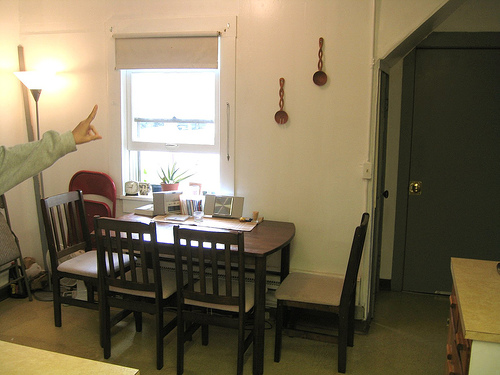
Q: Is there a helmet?
A: No, there are no helmets.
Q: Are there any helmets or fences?
A: No, there are no helmets or fences.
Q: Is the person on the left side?
A: Yes, the person is on the left of the image.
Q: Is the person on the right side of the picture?
A: No, the person is on the left of the image.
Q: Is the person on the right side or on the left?
A: The person is on the left of the image.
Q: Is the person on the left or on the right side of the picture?
A: The person is on the left of the image.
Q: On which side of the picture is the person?
A: The person is on the left of the image.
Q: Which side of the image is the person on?
A: The person is on the left of the image.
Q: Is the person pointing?
A: Yes, the person is pointing.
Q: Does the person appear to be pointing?
A: Yes, the person is pointing.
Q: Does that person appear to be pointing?
A: Yes, the person is pointing.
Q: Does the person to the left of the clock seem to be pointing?
A: Yes, the person is pointing.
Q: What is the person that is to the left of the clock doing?
A: The person is pointing.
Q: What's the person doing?
A: The person is pointing.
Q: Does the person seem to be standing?
A: No, the person is pointing.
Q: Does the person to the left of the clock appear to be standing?
A: No, the person is pointing.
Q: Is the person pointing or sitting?
A: The person is pointing.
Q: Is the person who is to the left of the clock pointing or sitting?
A: The person is pointing.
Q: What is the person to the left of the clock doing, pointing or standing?
A: The person is pointing.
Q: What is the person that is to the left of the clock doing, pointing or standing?
A: The person is pointing.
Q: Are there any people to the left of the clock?
A: Yes, there is a person to the left of the clock.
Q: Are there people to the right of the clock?
A: No, the person is to the left of the clock.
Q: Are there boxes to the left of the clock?
A: No, there is a person to the left of the clock.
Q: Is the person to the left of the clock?
A: Yes, the person is to the left of the clock.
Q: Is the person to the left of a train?
A: No, the person is to the left of the clock.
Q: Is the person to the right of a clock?
A: No, the person is to the left of a clock.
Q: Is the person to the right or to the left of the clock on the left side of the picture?
A: The person is to the left of the clock.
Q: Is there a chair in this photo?
A: Yes, there is a chair.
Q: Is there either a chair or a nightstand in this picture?
A: Yes, there is a chair.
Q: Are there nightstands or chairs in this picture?
A: Yes, there is a chair.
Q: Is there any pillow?
A: No, there are no pillows.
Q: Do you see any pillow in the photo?
A: No, there are no pillows.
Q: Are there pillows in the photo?
A: No, there are no pillows.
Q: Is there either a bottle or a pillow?
A: No, there are no pillows or bottles.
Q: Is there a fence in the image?
A: No, there are no fences.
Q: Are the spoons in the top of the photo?
A: Yes, the spoons are in the top of the image.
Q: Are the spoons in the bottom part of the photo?
A: No, the spoons are in the top of the image.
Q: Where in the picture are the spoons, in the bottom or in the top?
A: The spoons are in the top of the image.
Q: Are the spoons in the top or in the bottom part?
A: The spoons are in the top of the image.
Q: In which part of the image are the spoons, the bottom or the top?
A: The spoons are in the top of the image.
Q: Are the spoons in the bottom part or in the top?
A: The spoons are in the top of the image.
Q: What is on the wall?
A: The spoons are on the wall.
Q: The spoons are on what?
A: The spoons are on the wall.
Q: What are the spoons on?
A: The spoons are on the wall.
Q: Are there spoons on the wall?
A: Yes, there are spoons on the wall.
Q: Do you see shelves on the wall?
A: No, there are spoons on the wall.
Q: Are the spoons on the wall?
A: Yes, the spoons are on the wall.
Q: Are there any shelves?
A: No, there are no shelves.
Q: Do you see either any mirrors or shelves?
A: No, there are no shelves or mirrors.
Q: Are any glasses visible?
A: No, there are no glasses.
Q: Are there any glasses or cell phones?
A: No, there are no glasses or cell phones.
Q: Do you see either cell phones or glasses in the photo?
A: No, there are no glasses or cell phones.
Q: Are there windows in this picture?
A: Yes, there is a window.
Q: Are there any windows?
A: Yes, there is a window.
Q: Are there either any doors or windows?
A: Yes, there is a window.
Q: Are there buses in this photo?
A: No, there are no buses.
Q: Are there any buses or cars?
A: No, there are no buses or cars.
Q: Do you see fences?
A: No, there are no fences.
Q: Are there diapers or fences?
A: No, there are no fences or diapers.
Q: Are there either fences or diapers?
A: No, there are no fences or diapers.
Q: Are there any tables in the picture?
A: Yes, there is a table.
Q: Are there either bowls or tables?
A: Yes, there is a table.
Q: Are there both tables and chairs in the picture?
A: Yes, there are both a table and chairs.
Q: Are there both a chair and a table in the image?
A: Yes, there are both a table and a chair.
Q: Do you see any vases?
A: No, there are no vases.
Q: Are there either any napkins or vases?
A: No, there are no vases or napkins.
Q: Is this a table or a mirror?
A: This is a table.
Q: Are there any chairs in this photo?
A: Yes, there is a chair.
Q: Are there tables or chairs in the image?
A: Yes, there is a chair.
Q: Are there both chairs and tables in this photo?
A: Yes, there are both a chair and a table.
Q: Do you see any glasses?
A: No, there are no glasses.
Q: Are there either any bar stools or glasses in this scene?
A: No, there are no glasses or bar stools.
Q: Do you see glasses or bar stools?
A: No, there are no glasses or bar stools.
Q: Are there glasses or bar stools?
A: No, there are no glasses or bar stools.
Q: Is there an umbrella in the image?
A: No, there are no umbrellas.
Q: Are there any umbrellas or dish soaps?
A: No, there are no umbrellas or dish soaps.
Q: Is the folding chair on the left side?
A: Yes, the folding chair is on the left of the image.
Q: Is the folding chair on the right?
A: No, the folding chair is on the left of the image.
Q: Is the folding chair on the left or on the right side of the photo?
A: The folding chair is on the left of the image.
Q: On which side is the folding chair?
A: The folding chair is on the left of the image.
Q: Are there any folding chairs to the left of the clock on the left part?
A: Yes, there is a folding chair to the left of the clock.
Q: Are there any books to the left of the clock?
A: No, there is a folding chair to the left of the clock.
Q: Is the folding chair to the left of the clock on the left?
A: Yes, the folding chair is to the left of the clock.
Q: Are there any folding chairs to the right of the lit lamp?
A: Yes, there is a folding chair to the right of the lamp.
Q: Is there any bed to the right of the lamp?
A: No, there is a folding chair to the right of the lamp.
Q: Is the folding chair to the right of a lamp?
A: Yes, the folding chair is to the right of a lamp.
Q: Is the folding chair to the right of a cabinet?
A: No, the folding chair is to the right of a lamp.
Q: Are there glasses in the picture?
A: No, there are no glasses.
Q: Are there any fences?
A: No, there are no fences.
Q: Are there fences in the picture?
A: No, there are no fences.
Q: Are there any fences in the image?
A: No, there are no fences.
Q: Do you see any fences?
A: No, there are no fences.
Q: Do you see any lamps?
A: Yes, there is a lamp.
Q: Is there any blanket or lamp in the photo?
A: Yes, there is a lamp.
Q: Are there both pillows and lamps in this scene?
A: No, there is a lamp but no pillows.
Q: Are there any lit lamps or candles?
A: Yes, there is a lit lamp.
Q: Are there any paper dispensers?
A: No, there are no paper dispensers.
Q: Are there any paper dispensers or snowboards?
A: No, there are no paper dispensers or snowboards.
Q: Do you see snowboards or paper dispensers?
A: No, there are no paper dispensers or snowboards.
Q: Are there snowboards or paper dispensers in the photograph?
A: No, there are no paper dispensers or snowboards.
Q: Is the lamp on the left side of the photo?
A: Yes, the lamp is on the left of the image.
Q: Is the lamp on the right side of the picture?
A: No, the lamp is on the left of the image.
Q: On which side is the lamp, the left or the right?
A: The lamp is on the left of the image.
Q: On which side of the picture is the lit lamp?
A: The lamp is on the left of the image.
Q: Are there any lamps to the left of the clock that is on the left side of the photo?
A: Yes, there is a lamp to the left of the clock.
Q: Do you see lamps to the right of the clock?
A: No, the lamp is to the left of the clock.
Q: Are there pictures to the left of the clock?
A: No, there is a lamp to the left of the clock.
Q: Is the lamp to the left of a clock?
A: Yes, the lamp is to the left of a clock.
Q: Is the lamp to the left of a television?
A: No, the lamp is to the left of a clock.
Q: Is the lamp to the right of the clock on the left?
A: No, the lamp is to the left of the clock.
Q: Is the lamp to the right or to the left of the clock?
A: The lamp is to the left of the clock.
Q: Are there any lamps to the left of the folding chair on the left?
A: Yes, there is a lamp to the left of the folding chair.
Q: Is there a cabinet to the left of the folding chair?
A: No, there is a lamp to the left of the folding chair.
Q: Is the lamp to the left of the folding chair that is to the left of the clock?
A: Yes, the lamp is to the left of the folding chair.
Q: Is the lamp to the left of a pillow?
A: No, the lamp is to the left of the folding chair.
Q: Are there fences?
A: No, there are no fences.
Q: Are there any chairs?
A: Yes, there is a chair.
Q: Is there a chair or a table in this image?
A: Yes, there is a chair.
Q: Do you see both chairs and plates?
A: No, there is a chair but no plates.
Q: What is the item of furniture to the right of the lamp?
A: The piece of furniture is a chair.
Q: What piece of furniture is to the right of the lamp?
A: The piece of furniture is a chair.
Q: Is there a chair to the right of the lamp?
A: Yes, there is a chair to the right of the lamp.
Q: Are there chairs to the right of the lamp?
A: Yes, there is a chair to the right of the lamp.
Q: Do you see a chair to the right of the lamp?
A: Yes, there is a chair to the right of the lamp.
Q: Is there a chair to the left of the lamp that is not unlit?
A: No, the chair is to the right of the lamp.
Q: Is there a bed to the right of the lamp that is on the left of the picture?
A: No, there is a chair to the right of the lamp.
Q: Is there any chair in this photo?
A: Yes, there is a chair.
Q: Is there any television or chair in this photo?
A: Yes, there is a chair.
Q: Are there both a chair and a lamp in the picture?
A: Yes, there are both a chair and a lamp.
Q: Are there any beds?
A: No, there are no beds.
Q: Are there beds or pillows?
A: No, there are no beds or pillows.